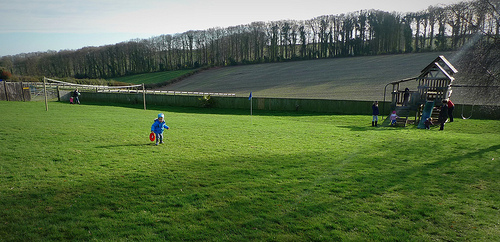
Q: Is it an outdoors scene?
A: Yes, it is outdoors.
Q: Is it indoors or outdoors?
A: It is outdoors.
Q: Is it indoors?
A: No, it is outdoors.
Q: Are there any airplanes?
A: No, there are no airplanes.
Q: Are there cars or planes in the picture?
A: No, there are no planes or cars.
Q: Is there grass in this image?
A: Yes, there is grass.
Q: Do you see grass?
A: Yes, there is grass.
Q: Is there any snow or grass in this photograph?
A: Yes, there is grass.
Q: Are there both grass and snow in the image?
A: No, there is grass but no snow.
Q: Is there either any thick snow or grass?
A: Yes, there is thick grass.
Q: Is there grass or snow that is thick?
A: Yes, the grass is thick.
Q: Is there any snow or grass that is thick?
A: Yes, the grass is thick.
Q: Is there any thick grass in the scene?
A: Yes, there is thick grass.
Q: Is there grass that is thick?
A: Yes, there is grass that is thick.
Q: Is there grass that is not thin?
A: Yes, there is thick grass.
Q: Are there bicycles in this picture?
A: No, there are no bicycles.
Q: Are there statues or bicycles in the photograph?
A: No, there are no bicycles or statues.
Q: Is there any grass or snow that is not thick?
A: No, there is grass but it is thick.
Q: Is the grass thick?
A: Yes, the grass is thick.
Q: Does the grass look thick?
A: Yes, the grass is thick.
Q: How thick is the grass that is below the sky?
A: The grass is thick.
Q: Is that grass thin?
A: No, the grass is thick.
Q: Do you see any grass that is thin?
A: No, there is grass but it is thick.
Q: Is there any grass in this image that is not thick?
A: No, there is grass but it is thick.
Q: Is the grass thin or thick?
A: The grass is thick.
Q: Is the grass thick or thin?
A: The grass is thick.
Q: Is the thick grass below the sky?
A: Yes, the grass is below the sky.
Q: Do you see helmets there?
A: No, there are no helmets.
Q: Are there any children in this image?
A: Yes, there are children.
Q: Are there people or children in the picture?
A: Yes, there are children.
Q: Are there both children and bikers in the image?
A: No, there are children but no bikers.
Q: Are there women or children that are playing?
A: Yes, the children are playing.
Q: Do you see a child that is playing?
A: Yes, there are children that are playing.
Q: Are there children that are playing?
A: Yes, there are children that are playing.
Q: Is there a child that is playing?
A: Yes, there are children that are playing.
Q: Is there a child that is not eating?
A: Yes, there are children that are playing.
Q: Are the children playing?
A: Yes, the children are playing.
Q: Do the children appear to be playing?
A: Yes, the children are playing.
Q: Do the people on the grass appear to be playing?
A: Yes, the children are playing.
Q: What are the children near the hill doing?
A: The children are playing.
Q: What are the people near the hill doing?
A: The children are playing.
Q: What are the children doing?
A: The children are playing.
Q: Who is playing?
A: The kids are playing.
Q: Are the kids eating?
A: No, the kids are playing.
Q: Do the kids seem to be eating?
A: No, the kids are playing.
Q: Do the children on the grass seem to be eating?
A: No, the children are playing.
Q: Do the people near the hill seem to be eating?
A: No, the children are playing.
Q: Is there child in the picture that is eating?
A: No, there are children but they are playing.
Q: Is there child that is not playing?
A: No, there are children but they are playing.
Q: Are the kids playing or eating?
A: The kids are playing.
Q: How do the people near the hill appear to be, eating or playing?
A: The kids are playing.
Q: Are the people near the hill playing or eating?
A: The kids are playing.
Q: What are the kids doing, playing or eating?
A: The kids are playing.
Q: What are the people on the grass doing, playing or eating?
A: The kids are playing.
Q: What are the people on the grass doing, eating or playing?
A: The kids are playing.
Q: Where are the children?
A: The children are on the grass.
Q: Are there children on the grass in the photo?
A: Yes, there are children on the grass.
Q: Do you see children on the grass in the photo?
A: Yes, there are children on the grass.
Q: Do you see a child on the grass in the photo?
A: Yes, there are children on the grass.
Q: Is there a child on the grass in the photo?
A: Yes, there are children on the grass.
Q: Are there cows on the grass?
A: No, there are children on the grass.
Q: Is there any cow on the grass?
A: No, there are children on the grass.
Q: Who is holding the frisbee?
A: The children are holding the frisbee.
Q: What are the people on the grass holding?
A: The children are holding the frisbee.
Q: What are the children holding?
A: The children are holding the frisbee.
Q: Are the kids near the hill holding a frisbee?
A: Yes, the children are holding a frisbee.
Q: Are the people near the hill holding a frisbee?
A: Yes, the children are holding a frisbee.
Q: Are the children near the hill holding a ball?
A: No, the children are holding a frisbee.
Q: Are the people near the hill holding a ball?
A: No, the children are holding a frisbee.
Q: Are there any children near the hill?
A: Yes, there are children near the hill.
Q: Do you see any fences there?
A: Yes, there is a fence.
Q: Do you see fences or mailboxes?
A: Yes, there is a fence.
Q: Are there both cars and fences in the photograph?
A: No, there is a fence but no cars.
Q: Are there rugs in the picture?
A: No, there are no rugs.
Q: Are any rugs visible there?
A: No, there are no rugs.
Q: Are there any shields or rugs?
A: No, there are no rugs or shields.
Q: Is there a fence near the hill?
A: Yes, there is a fence near the hill.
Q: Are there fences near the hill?
A: Yes, there is a fence near the hill.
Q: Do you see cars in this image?
A: No, there are no cars.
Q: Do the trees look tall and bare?
A: Yes, the trees are tall and bare.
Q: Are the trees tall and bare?
A: Yes, the trees are tall and bare.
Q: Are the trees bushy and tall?
A: No, the trees are tall but bare.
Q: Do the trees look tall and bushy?
A: No, the trees are tall but bare.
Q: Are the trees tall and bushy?
A: No, the trees are tall but bare.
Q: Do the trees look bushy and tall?
A: No, the trees are tall but bare.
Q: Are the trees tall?
A: Yes, the trees are tall.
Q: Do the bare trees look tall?
A: Yes, the trees are tall.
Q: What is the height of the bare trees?
A: The trees are tall.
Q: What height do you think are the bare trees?
A: The trees are tall.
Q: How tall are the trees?
A: The trees are tall.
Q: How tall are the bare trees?
A: The trees are tall.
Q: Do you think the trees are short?
A: No, the trees are tall.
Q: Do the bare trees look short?
A: No, the trees are tall.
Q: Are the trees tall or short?
A: The trees are tall.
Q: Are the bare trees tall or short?
A: The trees are tall.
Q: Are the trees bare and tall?
A: Yes, the trees are bare and tall.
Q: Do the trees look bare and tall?
A: Yes, the trees are bare and tall.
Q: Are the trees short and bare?
A: No, the trees are bare but tall.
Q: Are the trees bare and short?
A: No, the trees are bare but tall.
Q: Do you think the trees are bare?
A: Yes, the trees are bare.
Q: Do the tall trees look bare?
A: Yes, the trees are bare.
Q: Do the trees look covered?
A: No, the trees are bare.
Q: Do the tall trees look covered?
A: No, the trees are bare.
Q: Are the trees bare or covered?
A: The trees are bare.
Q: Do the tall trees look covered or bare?
A: The trees are bare.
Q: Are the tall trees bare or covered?
A: The trees are bare.